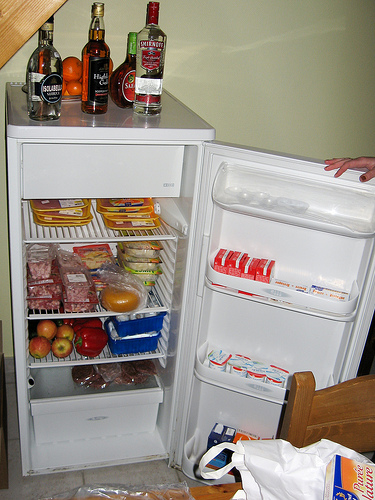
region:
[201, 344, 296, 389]
FOUR CONTAINERS OF YOGURT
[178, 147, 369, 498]
AN OPEN REFRIDGERATER DOOR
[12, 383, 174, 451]
A CRISPER DRAWER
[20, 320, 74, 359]
FOUR APPLES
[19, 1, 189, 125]
FOUR BOTTLES OF LIQUOR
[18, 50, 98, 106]
A PLATE OF ORANGES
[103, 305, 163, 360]
TWO CONTAINERS OF MUSHROOMS ON FIRST SHELF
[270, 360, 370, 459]
A BROWN WOODEN CHAIR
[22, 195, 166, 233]
EIGHT PACKAGES OF CHICKEN ON TOP SHELF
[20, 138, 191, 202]
A FREEZER COMPARTMENT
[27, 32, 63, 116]
Clear bottle of alcohol on a fridge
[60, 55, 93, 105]
Oranges on a white fridge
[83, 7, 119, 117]
Brown bottle of liquor on a fridge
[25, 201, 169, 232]
Packages of meat in a fridge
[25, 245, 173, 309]
Food in a fridge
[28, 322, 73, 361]
Apples in a fridge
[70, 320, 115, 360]
Red peppers in a fridge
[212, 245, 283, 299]
Fruit juice boxes in a fridge door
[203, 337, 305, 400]
Yogurt in a fridge door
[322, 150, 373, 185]
Hand on a fridge door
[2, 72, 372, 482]
Refrigerator is full.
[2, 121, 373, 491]
Refrigerator drawer is empty.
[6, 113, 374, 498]
Meat is on the top shelf.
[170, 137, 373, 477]
Yogurt is on the bottom shelf of door.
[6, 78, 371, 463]
Refrigerator door is open.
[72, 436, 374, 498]
White bag is on the table.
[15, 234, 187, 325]
Onion in a bag.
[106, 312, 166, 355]
Mushrooms in a container.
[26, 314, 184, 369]
Apples on the third shelf.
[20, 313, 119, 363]
Red peppers are beside the apples.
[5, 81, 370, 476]
a small white refrigerator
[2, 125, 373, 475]
the refrigerator is open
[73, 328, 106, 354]
red pepper in the refrigerator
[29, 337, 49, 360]
an apple in the refrigertaor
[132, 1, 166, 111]
a bottle of vodka on top of the refrigerator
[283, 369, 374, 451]
a brown chair in front of the refigerator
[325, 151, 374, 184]
a hand holds the refrigerator door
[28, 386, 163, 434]
crisper drawer in the refrigerator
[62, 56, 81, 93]
oranges on top of the refrigerator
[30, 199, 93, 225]
foam meat trays in the refrigerator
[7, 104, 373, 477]
The mini refrigerator is open.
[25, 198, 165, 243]
Choice meats line the top shelf.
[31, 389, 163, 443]
The vegetable drawer is empty.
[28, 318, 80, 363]
Fresh apples to snack on.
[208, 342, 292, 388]
Some healthy yogurt sure to satisfy.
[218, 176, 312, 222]
Someone forgot to buy eggs.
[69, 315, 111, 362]
Nice red peppers from the garden.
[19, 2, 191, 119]
Alcoholic beverages on top of the refrigerator.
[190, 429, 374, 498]
Bags on the table to unpack.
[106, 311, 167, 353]
Mushrooms to saute in butter.